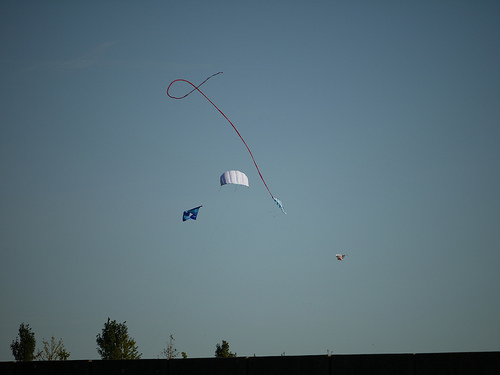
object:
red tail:
[165, 70, 274, 198]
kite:
[181, 204, 203, 222]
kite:
[218, 170, 251, 187]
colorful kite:
[335, 254, 348, 262]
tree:
[9, 321, 37, 362]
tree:
[35, 333, 71, 363]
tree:
[95, 317, 143, 360]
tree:
[214, 339, 238, 358]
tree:
[159, 332, 180, 359]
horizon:
[0, 349, 499, 364]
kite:
[165, 71, 288, 215]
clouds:
[4, 3, 498, 365]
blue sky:
[0, 0, 498, 358]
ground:
[2, 351, 500, 374]